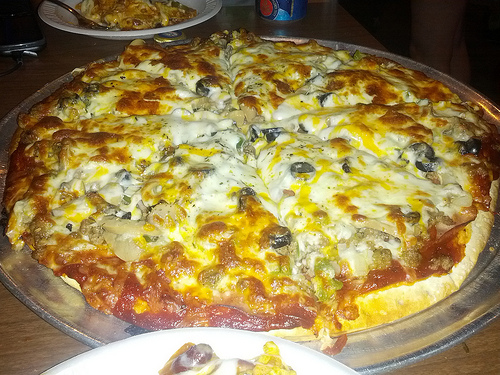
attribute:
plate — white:
[37, 1, 226, 39]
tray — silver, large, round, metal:
[1, 35, 497, 375]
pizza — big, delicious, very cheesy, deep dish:
[9, 38, 497, 330]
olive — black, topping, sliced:
[292, 161, 318, 174]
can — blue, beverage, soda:
[256, 0, 306, 23]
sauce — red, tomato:
[367, 230, 464, 286]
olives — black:
[248, 122, 293, 144]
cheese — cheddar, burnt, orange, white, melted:
[85, 67, 182, 162]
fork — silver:
[46, 0, 107, 32]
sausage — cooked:
[427, 201, 478, 245]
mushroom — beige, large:
[100, 212, 156, 265]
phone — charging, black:
[1, 2, 45, 58]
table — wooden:
[309, 3, 385, 43]